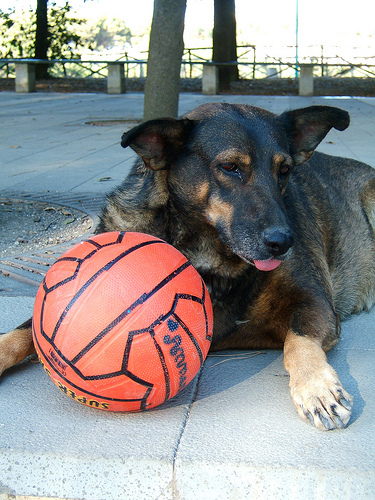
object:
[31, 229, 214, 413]
ball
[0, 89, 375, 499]
ground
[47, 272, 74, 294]
lines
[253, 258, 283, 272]
tongue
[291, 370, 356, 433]
paw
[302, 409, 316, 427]
nails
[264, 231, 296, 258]
nose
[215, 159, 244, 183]
eyes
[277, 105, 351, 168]
ears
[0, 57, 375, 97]
benches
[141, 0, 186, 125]
tree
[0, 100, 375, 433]
brindle dog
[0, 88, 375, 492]
sidewalk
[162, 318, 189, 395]
writing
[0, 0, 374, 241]
background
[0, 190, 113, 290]
drain cover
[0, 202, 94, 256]
dirt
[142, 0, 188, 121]
tree trunk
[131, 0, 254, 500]
middle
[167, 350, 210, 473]
crack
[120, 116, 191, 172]
ear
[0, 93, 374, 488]
concrete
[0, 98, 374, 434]
down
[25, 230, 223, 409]
football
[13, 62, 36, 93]
pillar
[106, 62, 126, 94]
pillar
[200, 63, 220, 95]
pillar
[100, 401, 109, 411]
letters